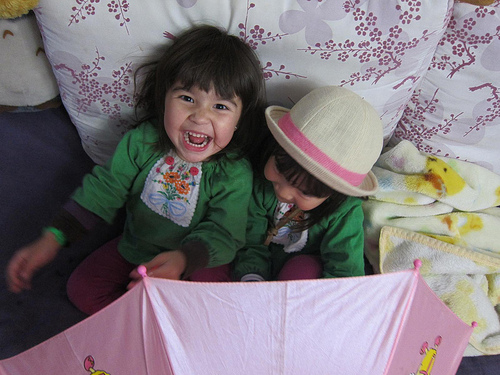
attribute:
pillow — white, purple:
[384, 4, 499, 174]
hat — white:
[258, 87, 380, 190]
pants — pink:
[93, 223, 268, 298]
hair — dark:
[135, 17, 276, 142]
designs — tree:
[333, 17, 435, 89]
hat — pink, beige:
[261, 83, 382, 198]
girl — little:
[60, 30, 270, 252]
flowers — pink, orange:
[147, 154, 198, 219]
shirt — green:
[57, 120, 254, 279]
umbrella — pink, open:
[9, 231, 484, 373]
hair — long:
[132, 23, 259, 163]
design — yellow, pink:
[403, 333, 456, 370]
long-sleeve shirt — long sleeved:
[37, 122, 252, 269]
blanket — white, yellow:
[400, 119, 497, 360]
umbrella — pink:
[1, 256, 481, 373]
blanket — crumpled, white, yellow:
[365, 141, 499, 353]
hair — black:
[153, 19, 270, 161]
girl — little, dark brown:
[248, 90, 373, 277]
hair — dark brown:
[292, 168, 339, 226]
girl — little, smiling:
[0, 26, 262, 322]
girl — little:
[239, 85, 370, 277]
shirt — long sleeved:
[105, 127, 275, 265]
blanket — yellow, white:
[329, 24, 499, 373]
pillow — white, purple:
[32, 1, 455, 209]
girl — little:
[186, 86, 386, 280]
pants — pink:
[67, 236, 233, 315]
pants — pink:
[276, 251, 322, 279]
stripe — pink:
[276, 109, 367, 187]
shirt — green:
[234, 178, 366, 277]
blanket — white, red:
[33, 2, 498, 166]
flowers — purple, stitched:
[428, 6, 499, 79]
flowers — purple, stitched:
[465, 79, 499, 135]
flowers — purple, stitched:
[388, 86, 465, 157]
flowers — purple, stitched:
[298, 1, 438, 89]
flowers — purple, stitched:
[233, 2, 310, 82]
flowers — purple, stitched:
[49, 46, 136, 126]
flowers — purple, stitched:
[64, 0, 134, 38]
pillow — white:
[33, 0, 454, 163]